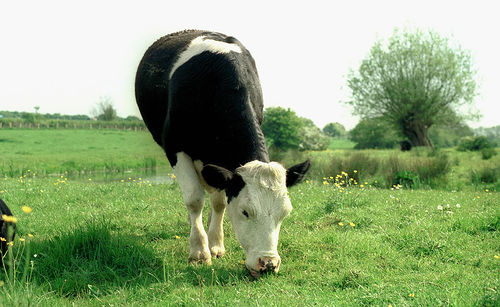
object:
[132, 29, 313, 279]
cow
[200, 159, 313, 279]
head.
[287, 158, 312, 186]
ears.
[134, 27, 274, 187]
body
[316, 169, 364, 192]
yellow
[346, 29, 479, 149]
tree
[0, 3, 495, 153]
background.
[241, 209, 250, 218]
eyes.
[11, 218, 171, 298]
patch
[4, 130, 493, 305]
ground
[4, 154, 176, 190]
pond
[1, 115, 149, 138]
fence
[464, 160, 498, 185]
bush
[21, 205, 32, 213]
flowers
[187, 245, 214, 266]
feet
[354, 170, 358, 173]
flowers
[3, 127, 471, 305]
grass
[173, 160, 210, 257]
legs